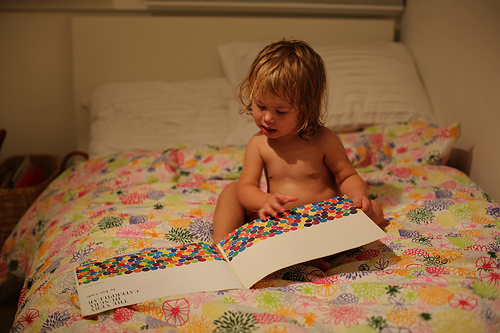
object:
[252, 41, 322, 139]
head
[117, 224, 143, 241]
flower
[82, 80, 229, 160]
pillow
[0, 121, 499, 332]
bed spread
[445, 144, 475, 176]
shadow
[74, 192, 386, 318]
children's book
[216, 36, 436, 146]
pillows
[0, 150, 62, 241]
basket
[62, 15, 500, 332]
bed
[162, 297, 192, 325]
flower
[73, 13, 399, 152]
panel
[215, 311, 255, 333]
flower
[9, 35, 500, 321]
comforter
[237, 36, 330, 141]
blonde hair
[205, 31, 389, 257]
child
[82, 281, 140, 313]
words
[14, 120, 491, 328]
bread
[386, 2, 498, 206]
wall